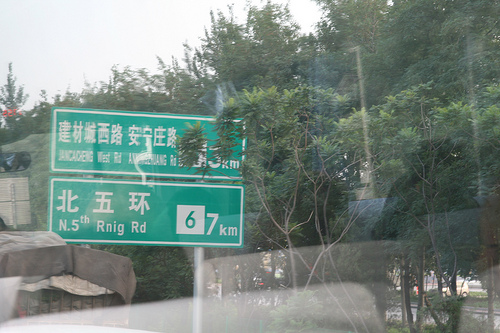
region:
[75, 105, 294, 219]
sign on a pole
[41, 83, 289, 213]
sing on a metal pole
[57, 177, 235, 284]
pole with sign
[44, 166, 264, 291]
metal pole with sign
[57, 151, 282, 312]
green sign on pole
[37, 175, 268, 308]
green sign on metal pole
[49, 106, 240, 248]
green and white highway sign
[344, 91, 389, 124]
green leaves in brown tree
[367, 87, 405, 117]
green leaves in brown tree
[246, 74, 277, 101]
green leaves in brown tree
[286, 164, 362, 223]
green leaves in brown tree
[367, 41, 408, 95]
green leaves in brown tree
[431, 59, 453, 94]
green leaves in brown tree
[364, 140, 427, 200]
green leaves in brown tree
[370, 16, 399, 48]
green leaves in brown tree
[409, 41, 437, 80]
green leaves in brown tree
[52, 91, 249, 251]
green and white sign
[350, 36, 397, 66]
green leaves in brown tree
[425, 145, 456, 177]
green leaves in brown tree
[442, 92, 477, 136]
green leaves in brown tree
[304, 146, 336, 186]
green leaves in brown tree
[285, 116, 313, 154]
green leaves in brown tree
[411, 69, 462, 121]
green leaves in brown tree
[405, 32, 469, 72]
green leaves in brown tree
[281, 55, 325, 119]
green leaves in brown tree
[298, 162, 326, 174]
v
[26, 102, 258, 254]
white and green signs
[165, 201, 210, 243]
number six on sign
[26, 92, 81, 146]
corner of the sign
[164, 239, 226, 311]
pole under the sign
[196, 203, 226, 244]
white number seven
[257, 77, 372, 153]
leaves on the tree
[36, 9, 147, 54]
sky above the trees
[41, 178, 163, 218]
three large symbols on sign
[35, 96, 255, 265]
green and white sign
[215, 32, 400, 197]
trees behind street sign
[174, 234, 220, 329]
silver metal post of sign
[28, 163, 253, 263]
bottom green and white sign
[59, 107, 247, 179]
this is a road sighn